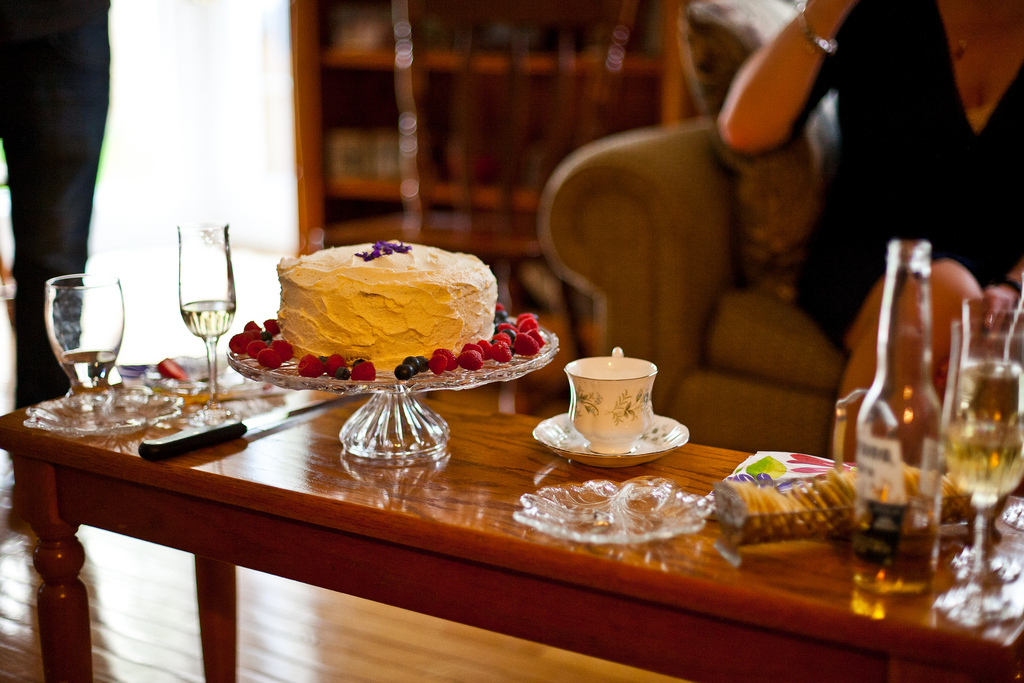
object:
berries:
[225, 316, 561, 396]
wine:
[180, 301, 237, 338]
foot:
[8, 453, 93, 683]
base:
[339, 391, 452, 468]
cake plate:
[225, 316, 559, 461]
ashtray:
[512, 475, 715, 545]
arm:
[715, 0, 860, 157]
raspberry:
[350, 361, 377, 381]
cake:
[228, 239, 545, 382]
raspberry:
[298, 354, 325, 378]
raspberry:
[255, 348, 282, 371]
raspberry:
[455, 350, 483, 372]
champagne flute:
[931, 293, 1024, 627]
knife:
[139, 393, 375, 463]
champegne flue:
[176, 220, 242, 430]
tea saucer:
[532, 413, 690, 468]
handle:
[137, 419, 247, 462]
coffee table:
[0, 377, 1024, 683]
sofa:
[537, 0, 1024, 458]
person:
[718, 0, 1022, 467]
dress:
[731, 0, 1024, 352]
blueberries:
[353, 239, 411, 263]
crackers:
[714, 461, 1010, 569]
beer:
[851, 239, 949, 600]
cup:
[562, 346, 658, 454]